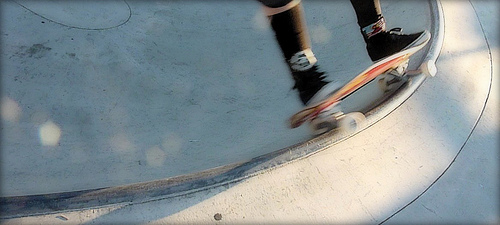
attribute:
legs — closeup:
[256, 1, 431, 105]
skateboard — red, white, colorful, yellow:
[287, 29, 438, 134]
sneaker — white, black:
[366, 28, 430, 62]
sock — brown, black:
[266, 2, 312, 59]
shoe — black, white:
[289, 62, 346, 104]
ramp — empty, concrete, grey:
[0, 2, 445, 217]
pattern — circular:
[20, 0, 132, 33]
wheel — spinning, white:
[310, 113, 345, 141]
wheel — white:
[421, 58, 438, 79]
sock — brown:
[352, 0, 384, 25]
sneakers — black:
[282, 22, 431, 106]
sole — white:
[304, 82, 345, 105]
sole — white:
[408, 31, 433, 50]